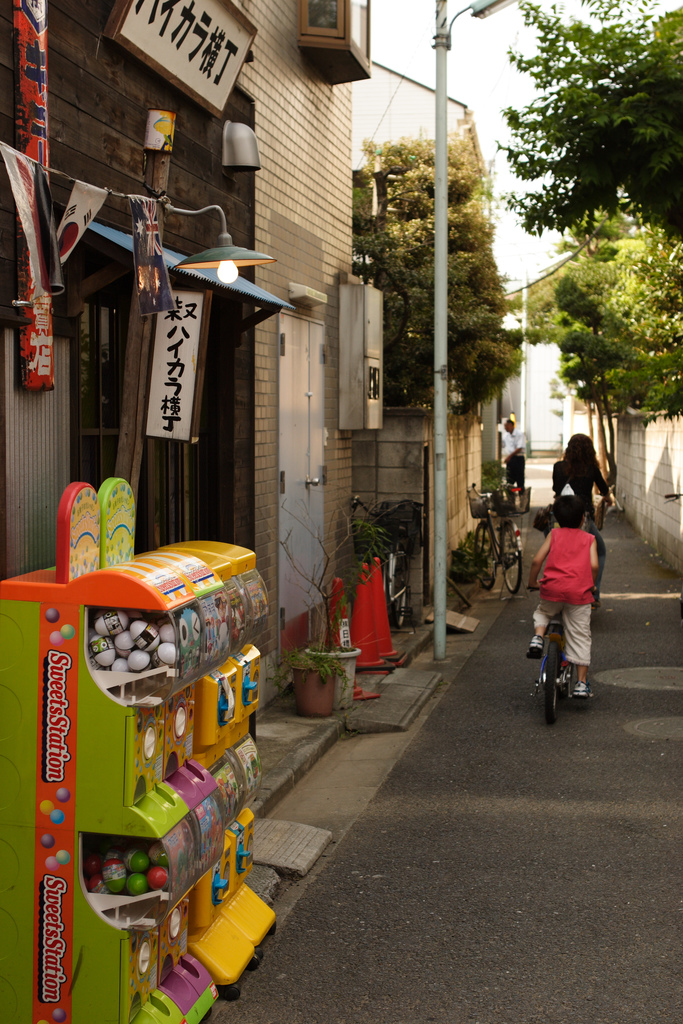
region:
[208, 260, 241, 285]
A light bulb lit up.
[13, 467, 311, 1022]
Toy vending machine.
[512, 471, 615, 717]
People on a bike.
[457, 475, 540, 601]
A parked bicycle.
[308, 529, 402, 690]
Orange cones.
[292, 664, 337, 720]
A brown flower pot.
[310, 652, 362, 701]
A grey flower pot.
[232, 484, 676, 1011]
An allyway.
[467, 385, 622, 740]
People in an ally.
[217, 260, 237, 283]
the light bulb is white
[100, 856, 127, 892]
the egg is red and green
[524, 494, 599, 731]
the child on the bike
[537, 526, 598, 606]
the sleeveless shirt is red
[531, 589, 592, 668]
the pants are beige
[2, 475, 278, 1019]
the toy machine is multi colored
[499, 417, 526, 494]
the man is standing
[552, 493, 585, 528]
the hair is black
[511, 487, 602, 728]
kid riding a bike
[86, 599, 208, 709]
various trinkets in the machine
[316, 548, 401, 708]
a group of orange traffic cones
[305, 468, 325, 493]
shiny doorknob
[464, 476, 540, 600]
bike is parked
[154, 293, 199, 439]
a row of black characters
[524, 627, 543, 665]
foot is on the pedal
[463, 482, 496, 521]
basket on the bike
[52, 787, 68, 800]
A small violet ball.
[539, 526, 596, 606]
A red sando of a boy.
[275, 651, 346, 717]
A red pot with grass.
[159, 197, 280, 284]
A hanging lampost is on.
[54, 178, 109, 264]
A flag of korea is hanging.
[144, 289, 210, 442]
Japanese writings on wooden board.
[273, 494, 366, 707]
A dead plant standing on white pot.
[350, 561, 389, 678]
A plain orange road cone.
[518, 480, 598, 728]
little boy is riding a bike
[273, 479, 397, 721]
plant is in a pot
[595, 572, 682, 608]
light is shining on the ground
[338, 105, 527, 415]
green leaves are on the tree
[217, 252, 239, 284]
light bulb is shining brightly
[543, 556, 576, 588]
wrinkles on the back of the shirt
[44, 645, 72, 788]
red writing on an orange background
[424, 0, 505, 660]
a tall gray light pole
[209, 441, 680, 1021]
a long paved road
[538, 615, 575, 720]
the back of a bike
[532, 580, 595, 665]
a boy's long shorts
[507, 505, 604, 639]
boy has red shirt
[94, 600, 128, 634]
toy prize in machine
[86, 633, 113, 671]
toy prize in machine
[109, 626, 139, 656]
toy prize in machine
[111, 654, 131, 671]
toy prize in machine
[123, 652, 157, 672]
toy prize in machine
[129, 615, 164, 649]
toy prize in machine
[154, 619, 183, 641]
toy prize in machine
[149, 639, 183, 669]
toy prize in machine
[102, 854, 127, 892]
toy prize in machine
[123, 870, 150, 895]
toy prize in machine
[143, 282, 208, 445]
white sign with black lettering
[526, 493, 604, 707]
young person with red tank top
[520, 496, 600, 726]
young child riding a bike on the path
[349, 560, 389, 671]
orange safety cone in front of white door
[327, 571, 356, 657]
orange safety cone in front of white door